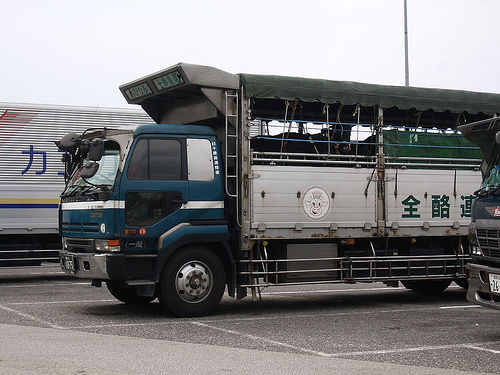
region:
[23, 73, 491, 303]
large blue and white truck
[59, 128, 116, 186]
side view mirrors on truck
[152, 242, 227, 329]
front black wheel of truck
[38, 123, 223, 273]
blue and white front truck part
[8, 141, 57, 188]
japanese lettering on truck side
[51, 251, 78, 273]
license plate on truck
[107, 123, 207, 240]
side door on truck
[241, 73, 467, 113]
green roof on back of truck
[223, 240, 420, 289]
metal steps on side of truck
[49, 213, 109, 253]
front grill of the truck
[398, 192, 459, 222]
foreign writing painted in green on truck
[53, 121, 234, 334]
passenger cab of large blue truck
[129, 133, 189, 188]
dark tinted glass window on truck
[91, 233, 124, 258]
headlight with orange turn signal flasher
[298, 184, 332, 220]
logo in white circle on silver trailer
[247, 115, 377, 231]
trailer with open section on top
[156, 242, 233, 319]
large black rubber tire on silver wheel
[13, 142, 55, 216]
foreign writing painted in blue on silver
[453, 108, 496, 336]
front of blue truck with chrome grille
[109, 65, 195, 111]
green and white signs on top of trailer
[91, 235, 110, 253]
a head light on the truck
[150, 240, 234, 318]
a wheel on the truck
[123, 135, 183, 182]
a window on the truck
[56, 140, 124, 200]
a windshield on the truck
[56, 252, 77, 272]
a license plate on the truck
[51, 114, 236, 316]
the cab of the truck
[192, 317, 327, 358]
a white line on the pavement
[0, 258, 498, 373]
gray asphalt pavement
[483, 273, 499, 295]
a white license plate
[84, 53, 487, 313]
truck on the road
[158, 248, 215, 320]
tire on the truck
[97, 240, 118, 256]
head light on the truck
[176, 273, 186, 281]
opening on the wheel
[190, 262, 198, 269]
opening on the wheel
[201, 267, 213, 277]
opening on the wheel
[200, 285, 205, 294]
opening on the wheel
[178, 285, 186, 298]
opening on the wheel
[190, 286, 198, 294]
opening on the wheel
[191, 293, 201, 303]
opening on the wheel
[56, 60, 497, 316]
A large white and blue truck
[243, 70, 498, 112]
A green tarp on a truck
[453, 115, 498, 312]
A large black truck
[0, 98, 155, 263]
A large white truck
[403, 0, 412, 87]
A tall metal pole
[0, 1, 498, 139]
A grey cloudy sky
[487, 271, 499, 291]
A white license plate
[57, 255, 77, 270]
A license plate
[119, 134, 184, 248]
The door on a truck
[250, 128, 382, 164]
some cows in a truck